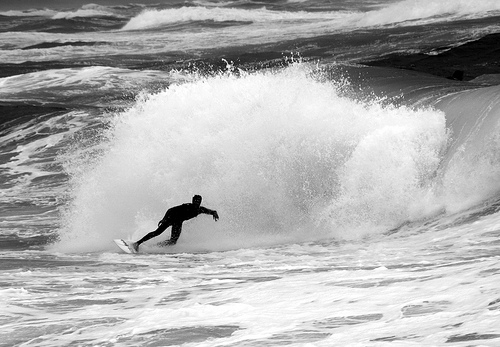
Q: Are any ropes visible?
A: No, there are no ropes.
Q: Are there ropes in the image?
A: No, there are no ropes.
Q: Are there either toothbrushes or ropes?
A: No, there are no ropes or toothbrushes.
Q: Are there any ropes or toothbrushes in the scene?
A: No, there are no ropes or toothbrushes.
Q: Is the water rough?
A: Yes, the water is rough.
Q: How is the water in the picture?
A: The water is rough.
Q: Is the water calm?
A: No, the water is rough.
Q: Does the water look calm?
A: No, the water is rough.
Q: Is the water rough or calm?
A: The water is rough.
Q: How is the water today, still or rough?
A: The water is rough.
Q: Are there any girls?
A: No, there are no girls.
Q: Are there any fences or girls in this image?
A: No, there are no girls or fences.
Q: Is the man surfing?
A: Yes, the man is surfing.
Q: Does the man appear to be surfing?
A: Yes, the man is surfing.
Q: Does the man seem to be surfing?
A: Yes, the man is surfing.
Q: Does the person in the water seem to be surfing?
A: Yes, the man is surfing.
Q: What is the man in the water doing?
A: The man is surfing.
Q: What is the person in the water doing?
A: The man is surfing.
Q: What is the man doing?
A: The man is surfing.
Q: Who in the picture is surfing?
A: The man is surfing.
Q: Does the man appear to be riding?
A: No, the man is surfing.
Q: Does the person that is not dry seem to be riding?
A: No, the man is surfing.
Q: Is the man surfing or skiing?
A: The man is surfing.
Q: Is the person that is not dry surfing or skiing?
A: The man is surfing.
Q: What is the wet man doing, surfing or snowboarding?
A: The man is surfing.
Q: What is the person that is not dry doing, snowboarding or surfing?
A: The man is surfing.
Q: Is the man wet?
A: Yes, the man is wet.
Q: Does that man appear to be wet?
A: Yes, the man is wet.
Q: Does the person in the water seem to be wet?
A: Yes, the man is wet.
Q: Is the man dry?
A: No, the man is wet.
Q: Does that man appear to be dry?
A: No, the man is wet.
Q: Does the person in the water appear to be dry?
A: No, the man is wet.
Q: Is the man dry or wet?
A: The man is wet.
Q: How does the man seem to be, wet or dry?
A: The man is wet.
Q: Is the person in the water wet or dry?
A: The man is wet.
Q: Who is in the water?
A: The man is in the water.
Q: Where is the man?
A: The man is in the water.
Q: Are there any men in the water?
A: Yes, there is a man in the water.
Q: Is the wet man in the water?
A: Yes, the man is in the water.